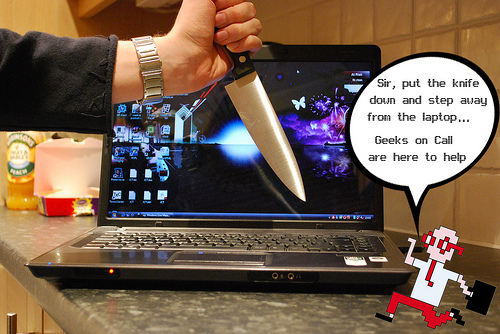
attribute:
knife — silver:
[174, 17, 316, 228]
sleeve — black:
[13, 5, 149, 161]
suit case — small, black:
[463, 276, 496, 321]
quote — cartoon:
[343, 58, 465, 195]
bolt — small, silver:
[228, 40, 274, 88]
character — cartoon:
[375, 226, 495, 330]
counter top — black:
[0, 205, 499, 332]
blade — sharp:
[220, 62, 316, 205]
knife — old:
[208, 9, 313, 206]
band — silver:
[119, 24, 175, 116]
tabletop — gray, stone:
[6, 203, 498, 330]